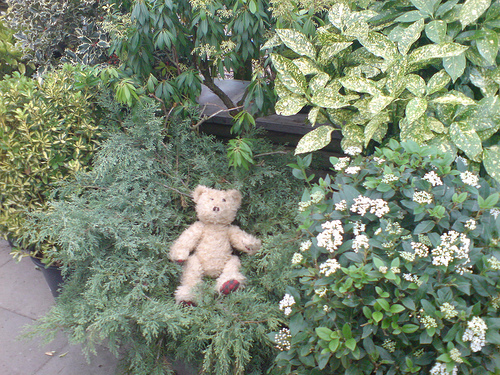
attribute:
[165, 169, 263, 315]
bear — brown, laying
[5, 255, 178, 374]
ground — grey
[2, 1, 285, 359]
bushes — green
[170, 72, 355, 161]
wall — black